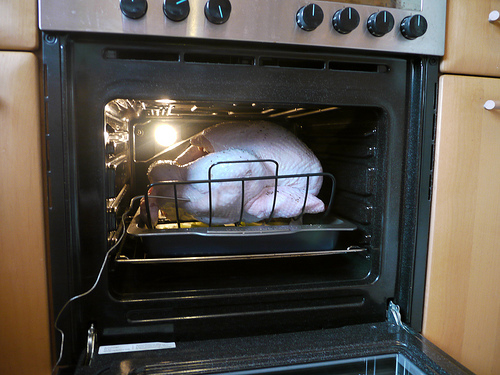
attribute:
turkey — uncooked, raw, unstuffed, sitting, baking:
[135, 118, 326, 224]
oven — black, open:
[39, 34, 437, 334]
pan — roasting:
[125, 203, 355, 252]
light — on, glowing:
[152, 124, 181, 152]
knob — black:
[298, 3, 324, 32]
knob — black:
[332, 7, 358, 34]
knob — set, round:
[369, 9, 395, 37]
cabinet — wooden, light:
[417, 74, 493, 372]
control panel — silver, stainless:
[37, 1, 446, 55]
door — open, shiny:
[72, 323, 469, 374]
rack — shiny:
[139, 160, 334, 222]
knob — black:
[205, 1, 231, 23]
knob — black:
[404, 15, 426, 40]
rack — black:
[117, 217, 367, 263]